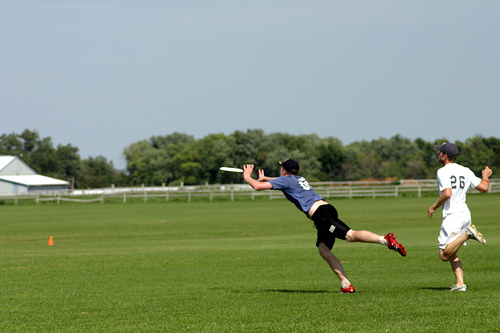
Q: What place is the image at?
A: It is at the field.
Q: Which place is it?
A: It is a field.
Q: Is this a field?
A: Yes, it is a field.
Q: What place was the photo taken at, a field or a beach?
A: It was taken at a field.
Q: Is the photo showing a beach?
A: No, the picture is showing a field.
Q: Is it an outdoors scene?
A: Yes, it is outdoors.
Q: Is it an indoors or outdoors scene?
A: It is outdoors.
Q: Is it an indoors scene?
A: No, it is outdoors.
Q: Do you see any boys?
A: No, there are no boys.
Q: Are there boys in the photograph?
A: No, there are no boys.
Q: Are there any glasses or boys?
A: No, there are no boys or glasses.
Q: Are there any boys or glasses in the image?
A: No, there are no boys or glasses.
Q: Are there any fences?
A: Yes, there is a fence.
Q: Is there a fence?
A: Yes, there is a fence.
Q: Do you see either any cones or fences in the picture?
A: Yes, there is a fence.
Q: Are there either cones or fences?
A: Yes, there is a fence.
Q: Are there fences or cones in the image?
A: Yes, there is a fence.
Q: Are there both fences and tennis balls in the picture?
A: No, there is a fence but no tennis balls.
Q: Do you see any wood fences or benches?
A: Yes, there is a wood fence.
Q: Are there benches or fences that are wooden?
A: Yes, the fence is wooden.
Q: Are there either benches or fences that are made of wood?
A: Yes, the fence is made of wood.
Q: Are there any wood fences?
A: Yes, there is a wood fence.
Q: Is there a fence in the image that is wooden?
A: Yes, there is a fence that is wooden.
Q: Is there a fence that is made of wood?
A: Yes, there is a fence that is made of wood.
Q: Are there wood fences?
A: Yes, there is a fence that is made of wood.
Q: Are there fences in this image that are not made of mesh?
A: Yes, there is a fence that is made of wood.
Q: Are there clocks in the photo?
A: No, there are no clocks.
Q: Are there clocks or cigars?
A: No, there are no clocks or cigars.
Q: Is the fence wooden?
A: Yes, the fence is wooden.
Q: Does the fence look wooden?
A: Yes, the fence is wooden.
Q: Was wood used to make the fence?
A: Yes, the fence is made of wood.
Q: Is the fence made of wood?
A: Yes, the fence is made of wood.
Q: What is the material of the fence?
A: The fence is made of wood.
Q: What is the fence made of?
A: The fence is made of wood.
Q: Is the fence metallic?
A: No, the fence is wooden.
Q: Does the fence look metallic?
A: No, the fence is wooden.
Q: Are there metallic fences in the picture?
A: No, there is a fence but it is wooden.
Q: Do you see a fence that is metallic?
A: No, there is a fence but it is wooden.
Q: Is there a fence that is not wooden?
A: No, there is a fence but it is wooden.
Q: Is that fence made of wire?
A: No, the fence is made of wood.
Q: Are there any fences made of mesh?
A: No, there is a fence but it is made of wood.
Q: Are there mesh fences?
A: No, there is a fence but it is made of wood.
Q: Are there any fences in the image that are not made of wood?
A: No, there is a fence but it is made of wood.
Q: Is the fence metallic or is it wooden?
A: The fence is wooden.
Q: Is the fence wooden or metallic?
A: The fence is wooden.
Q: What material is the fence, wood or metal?
A: The fence is made of wood.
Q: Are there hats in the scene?
A: Yes, there is a hat.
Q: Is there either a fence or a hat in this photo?
A: Yes, there is a hat.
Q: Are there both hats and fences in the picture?
A: Yes, there are both a hat and a fence.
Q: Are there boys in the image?
A: No, there are no boys.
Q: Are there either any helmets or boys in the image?
A: No, there are no boys or helmets.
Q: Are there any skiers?
A: No, there are no skiers.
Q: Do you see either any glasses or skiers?
A: No, there are no skiers or glasses.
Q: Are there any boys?
A: No, there are no boys.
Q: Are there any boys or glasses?
A: No, there are no boys or glasses.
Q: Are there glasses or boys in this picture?
A: No, there are no boys or glasses.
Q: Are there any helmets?
A: No, there are no helmets.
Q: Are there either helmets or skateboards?
A: No, there are no helmets or skateboards.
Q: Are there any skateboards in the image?
A: No, there are no skateboards.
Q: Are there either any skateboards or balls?
A: No, there are no skateboards or balls.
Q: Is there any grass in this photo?
A: Yes, there is grass.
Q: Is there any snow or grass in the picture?
A: Yes, there is grass.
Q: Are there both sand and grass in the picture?
A: No, there is grass but no sand.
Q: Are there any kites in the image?
A: No, there are no kites.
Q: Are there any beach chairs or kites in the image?
A: No, there are no kites or beach chairs.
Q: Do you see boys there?
A: No, there are no boys.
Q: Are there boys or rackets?
A: No, there are no boys or rackets.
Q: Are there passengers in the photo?
A: No, there are no passengers.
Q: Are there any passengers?
A: No, there are no passengers.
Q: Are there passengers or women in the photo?
A: No, there are no passengers or women.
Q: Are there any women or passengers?
A: No, there are no passengers or women.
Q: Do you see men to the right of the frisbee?
A: Yes, there is a man to the right of the frisbee.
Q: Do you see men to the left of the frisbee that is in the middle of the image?
A: No, the man is to the right of the frisbee.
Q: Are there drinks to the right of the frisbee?
A: No, there is a man to the right of the frisbee.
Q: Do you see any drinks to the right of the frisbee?
A: No, there is a man to the right of the frisbee.